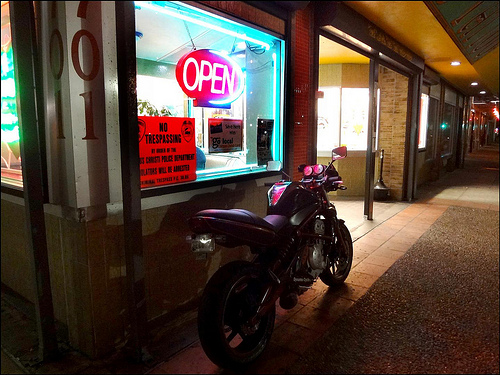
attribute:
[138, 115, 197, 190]
sign — orange, black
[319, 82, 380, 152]
window — uncovered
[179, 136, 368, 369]
motorcycle — parked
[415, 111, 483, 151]
lights — blue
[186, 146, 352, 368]
motorcycle — black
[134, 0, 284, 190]
window — large